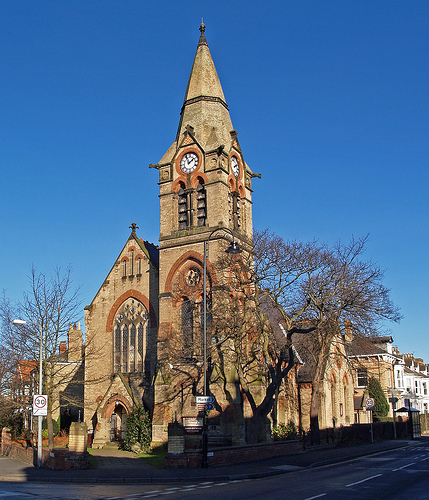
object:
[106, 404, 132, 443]
doorway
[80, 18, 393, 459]
church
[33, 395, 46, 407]
number 30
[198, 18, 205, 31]
steeple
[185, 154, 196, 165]
black hands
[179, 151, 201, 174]
clock face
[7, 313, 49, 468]
lamp